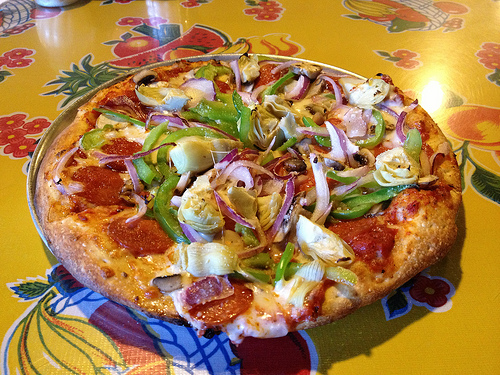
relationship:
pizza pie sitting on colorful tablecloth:
[24, 56, 461, 342] [331, 2, 488, 91]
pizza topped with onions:
[30, 46, 465, 345] [138, 55, 420, 241]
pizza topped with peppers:
[30, 46, 465, 345] [139, 85, 254, 230]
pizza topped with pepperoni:
[30, 46, 465, 345] [76, 129, 171, 249]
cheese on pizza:
[55, 62, 439, 344] [30, 46, 465, 345]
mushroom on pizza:
[347, 78, 390, 107] [30, 46, 465, 345]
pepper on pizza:
[130, 156, 161, 185] [30, 46, 465, 345]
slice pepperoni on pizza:
[183, 274, 253, 323] [30, 46, 465, 345]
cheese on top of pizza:
[171, 275, 317, 348] [33, 52, 461, 347]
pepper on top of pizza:
[335, 183, 412, 219] [33, 52, 461, 347]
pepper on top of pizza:
[149, 173, 184, 242] [33, 52, 461, 347]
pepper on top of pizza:
[235, 106, 252, 147] [33, 52, 461, 347]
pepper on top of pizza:
[193, 64, 233, 82] [33, 52, 461, 347]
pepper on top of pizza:
[353, 109, 383, 147] [33, 52, 461, 347]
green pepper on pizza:
[153, 172, 179, 242] [30, 46, 465, 345]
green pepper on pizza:
[120, 90, 271, 233] [35, 72, 460, 339]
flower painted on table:
[378, 43, 423, 70] [8, 2, 497, 371]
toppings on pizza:
[95, 79, 410, 293] [30, 46, 465, 345]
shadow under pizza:
[303, 330, 380, 354] [81, 69, 416, 306]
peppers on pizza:
[90, 65, 427, 280] [30, 46, 465, 345]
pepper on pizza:
[277, 235, 299, 285] [30, 46, 465, 345]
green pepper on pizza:
[85, 98, 140, 131] [30, 46, 465, 345]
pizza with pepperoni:
[30, 46, 465, 345] [72, 164, 124, 209]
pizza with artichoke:
[30, 46, 465, 345] [151, 172, 186, 240]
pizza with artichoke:
[30, 46, 465, 345] [329, 182, 409, 217]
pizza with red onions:
[30, 46, 465, 345] [308, 69, 370, 205]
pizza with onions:
[33, 52, 461, 347] [204, 139, 326, 245]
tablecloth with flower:
[0, 1, 495, 372] [383, 39, 420, 74]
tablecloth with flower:
[0, 1, 495, 372] [245, 0, 287, 31]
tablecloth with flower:
[0, 1, 495, 372] [2, 45, 34, 72]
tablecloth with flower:
[0, 1, 495, 372] [5, 106, 57, 165]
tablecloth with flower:
[0, 1, 495, 372] [412, 270, 456, 311]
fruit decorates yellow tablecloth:
[2, 1, 497, 373] [0, 0, 498, 374]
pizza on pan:
[30, 46, 465, 345] [18, 50, 368, 262]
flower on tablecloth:
[410, 281, 458, 312] [0, 1, 495, 372]